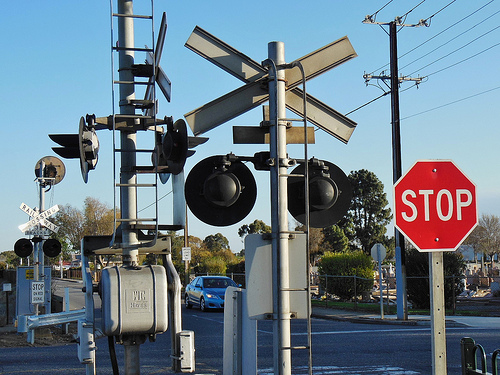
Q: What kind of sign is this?
A: A red and white stop sign.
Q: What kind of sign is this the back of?
A: A railroad crossing sign.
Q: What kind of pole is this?
A: A tall wood utility pole.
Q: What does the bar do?
A: Blocks cars.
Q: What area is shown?
A: A railroad crossing area.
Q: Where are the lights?
A: Over the train tracks.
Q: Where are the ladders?
A: On the lights.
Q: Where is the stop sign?
A: On the pole.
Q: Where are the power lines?
A: Connecting to the electric pole.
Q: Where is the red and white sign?
A: On a pole.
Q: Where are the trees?
A: Along the roadside.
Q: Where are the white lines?
A: On the road.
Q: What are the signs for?
A: The railroad crossing.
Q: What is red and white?
A: A stop sign.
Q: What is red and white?
A: A stop sign.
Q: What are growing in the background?
A: Bushes.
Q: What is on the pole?
A: A ladder.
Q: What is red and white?
A: A stop sign.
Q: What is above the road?
A: Power lines.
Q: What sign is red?
A: Stop sign.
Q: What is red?
A: Stop sign.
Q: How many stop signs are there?
A: One.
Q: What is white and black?
A: Railroad sign.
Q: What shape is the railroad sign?
A: X.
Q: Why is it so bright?
A: Sunshine.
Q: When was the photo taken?
A: Day time.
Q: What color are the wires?
A: Silver.